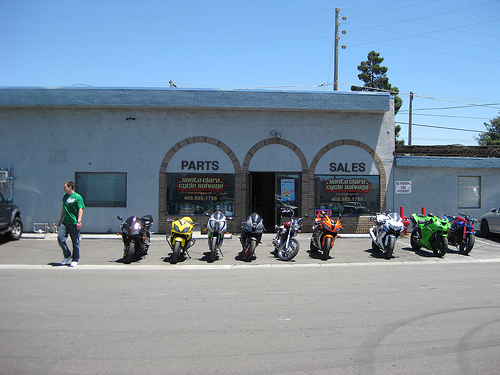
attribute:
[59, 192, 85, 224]
shirt — green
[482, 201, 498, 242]
automobile — white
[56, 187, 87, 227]
t-shirt — green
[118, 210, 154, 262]
bike — black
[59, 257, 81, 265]
shoes — white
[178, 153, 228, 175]
sign — white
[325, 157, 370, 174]
sign — white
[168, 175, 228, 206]
sign — white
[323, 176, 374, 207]
sign — white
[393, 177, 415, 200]
sign — white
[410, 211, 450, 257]
motorcycle — lime, green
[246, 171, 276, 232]
open door — opened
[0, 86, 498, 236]
auto store — parts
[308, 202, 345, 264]
motorcycle — orange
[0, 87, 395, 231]
store — motorcycle, parts, sales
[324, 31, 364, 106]
pole — telephone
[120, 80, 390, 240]
building — old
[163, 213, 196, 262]
motorcycle — yellow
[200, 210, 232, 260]
motorcycle — yellow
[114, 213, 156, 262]
motorcycle — yellow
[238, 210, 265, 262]
motorcycle — yellow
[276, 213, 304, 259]
motorcycle — yellow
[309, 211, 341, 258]
motorcycle — yellow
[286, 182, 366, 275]
motorcycle — orange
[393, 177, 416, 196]
sign — red, white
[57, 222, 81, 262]
jeans — blue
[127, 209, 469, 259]
motorcycles — nine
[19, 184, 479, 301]
motorcycles — bright, yellow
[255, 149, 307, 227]
door — dark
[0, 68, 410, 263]
building — old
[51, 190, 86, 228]
shirt — green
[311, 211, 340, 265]
motorcycle — orange, black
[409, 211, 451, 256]
bike — green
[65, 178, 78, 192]
hair — brown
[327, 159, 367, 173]
sales sign — black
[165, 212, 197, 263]
motorcycle — yellow and black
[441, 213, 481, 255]
motorcycle — red, blue